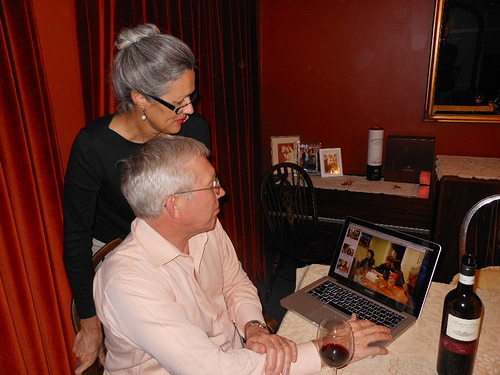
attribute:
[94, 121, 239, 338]
shirt — black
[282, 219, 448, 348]
laptop — open, silver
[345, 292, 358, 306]
key — black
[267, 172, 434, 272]
cabinet — wooden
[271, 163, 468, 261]
cabinet — wooden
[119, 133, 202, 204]
hair — white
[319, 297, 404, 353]
key — black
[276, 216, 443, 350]
computer — on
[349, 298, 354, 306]
key — black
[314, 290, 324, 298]
key — black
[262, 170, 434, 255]
cabinet — wooden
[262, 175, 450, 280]
cabinet — wooden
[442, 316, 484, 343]
label — white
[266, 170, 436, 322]
cabinet — wood, wooden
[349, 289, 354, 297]
key — black